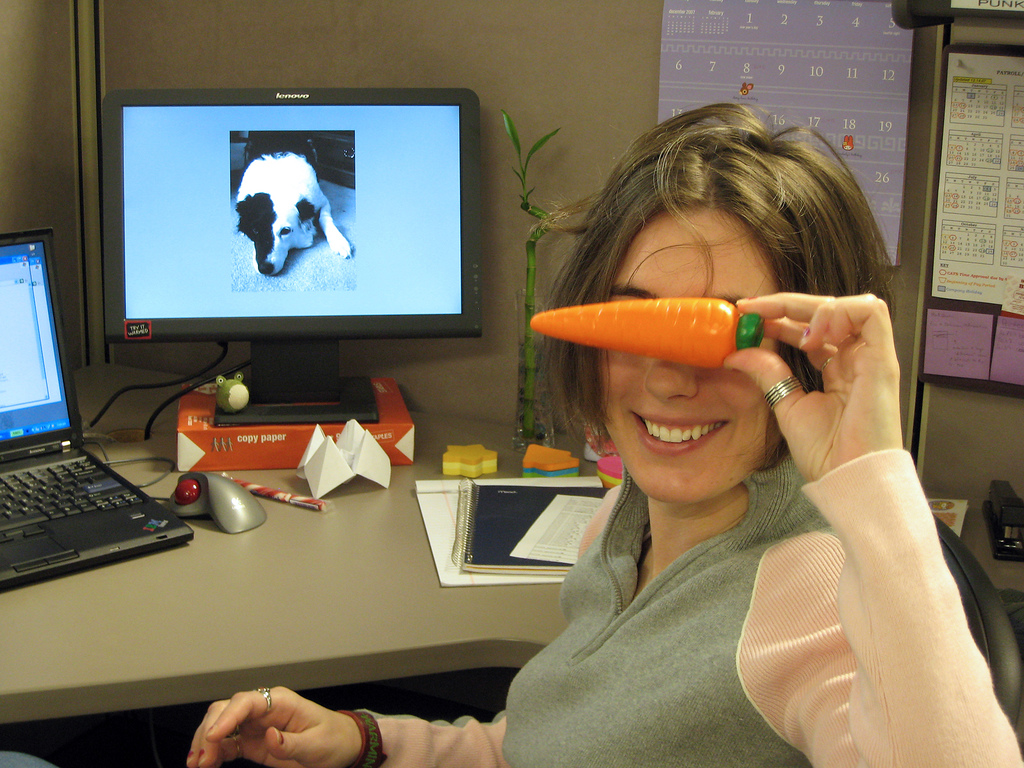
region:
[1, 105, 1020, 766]
woman holding a plastic carrot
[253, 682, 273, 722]
a silver ring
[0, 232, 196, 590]
an opened black laptop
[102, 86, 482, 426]
a black computer monitor on a black stand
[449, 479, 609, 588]
a dark blue spiral book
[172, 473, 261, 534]
a gray computer mouse with a red button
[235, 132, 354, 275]
a white and black dog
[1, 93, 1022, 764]
woman with short dark blonde hair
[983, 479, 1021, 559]
a black and silver stapler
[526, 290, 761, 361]
plastic carrot in the woman's hand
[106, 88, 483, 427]
monitor on the computer desk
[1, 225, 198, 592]
black laptop on the desk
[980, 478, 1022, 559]
black stapler on the desk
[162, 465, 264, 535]
red and gray mouse on the desk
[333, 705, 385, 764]
braclet on the woman's wrist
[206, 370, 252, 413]
toy frog on the monitor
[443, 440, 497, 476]
Colorful pad of paper on the desk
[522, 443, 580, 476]
Colorful pad of paper on the desk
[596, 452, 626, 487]
Colorful pad of paper on the desk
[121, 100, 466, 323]
Computer screen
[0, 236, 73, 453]
Computer screen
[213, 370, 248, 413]
Toy frog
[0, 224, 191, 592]
Laptop is visible on a desk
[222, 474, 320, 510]
Pen is laying on the desk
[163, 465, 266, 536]
Computer mouse is on the desk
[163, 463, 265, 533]
Gray computer mouse with a red roller ball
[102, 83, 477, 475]
Computer monitor sitting on a package of copy paper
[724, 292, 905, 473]
Hand with silver rings on the thumb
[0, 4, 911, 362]
Brown office partition wall with a calendar on it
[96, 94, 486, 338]
Image of a black and white dog on a computer screen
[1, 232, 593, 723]
Tan desk top with a laptop and some other items on it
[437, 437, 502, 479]
Yellow and white star shaped sticky note pad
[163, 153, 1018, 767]
Woman holding a plastic carrot in front of her eyes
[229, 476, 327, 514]
Pen with red and white candy cane stripes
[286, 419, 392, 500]
Fortune teller made with white paper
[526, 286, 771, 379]
small fake carrot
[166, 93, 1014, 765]
woman is holding a carrot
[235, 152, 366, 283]
picture of a dog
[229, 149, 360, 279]
black and white dog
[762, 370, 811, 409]
silver ring around the thumb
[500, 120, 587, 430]
green plant on the desk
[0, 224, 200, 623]
laptop is on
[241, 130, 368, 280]
black and white dog on computer monitor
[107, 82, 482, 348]
black flat screen computer monitor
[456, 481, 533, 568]
black spiral-bound notebook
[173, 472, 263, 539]
silver mouse with red wheel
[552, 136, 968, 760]
woman with gray and pink sweater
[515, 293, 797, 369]
a carrot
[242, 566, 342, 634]
the desk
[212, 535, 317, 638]
a brown desk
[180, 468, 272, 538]
a mouse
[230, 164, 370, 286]
a dog on the monitor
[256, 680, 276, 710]
women is wearing a ring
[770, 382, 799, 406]
a ring on thumb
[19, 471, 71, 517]
a keyboard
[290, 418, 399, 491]
a folded paper on the desk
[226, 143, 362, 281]
Picture of dog on computer screen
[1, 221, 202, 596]
Laptop computer on work desk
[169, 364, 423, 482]
Unopened package of copy paper on work desk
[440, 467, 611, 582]
Blue spiral notebook on work desk